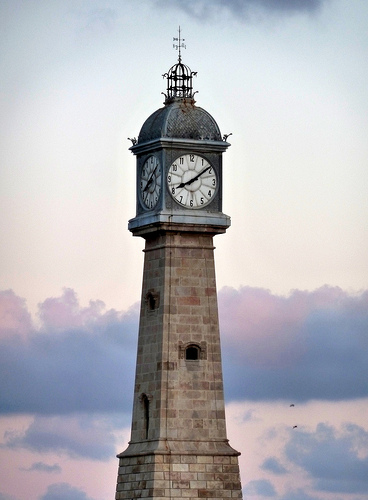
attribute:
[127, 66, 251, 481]
tower — atop, brick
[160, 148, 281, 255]
clock — brick, granite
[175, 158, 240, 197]
hand — minute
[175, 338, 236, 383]
window — large, small, under, opening, triangle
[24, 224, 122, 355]
sky — pink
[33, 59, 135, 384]
clouds — subtle, grey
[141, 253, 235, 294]
brick — white, brown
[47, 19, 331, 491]
photo — taken, evening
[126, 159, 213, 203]
numbers — gray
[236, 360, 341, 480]
birds — flying, distant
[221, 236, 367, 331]
shade — pink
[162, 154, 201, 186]
face — white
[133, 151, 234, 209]
time — displayed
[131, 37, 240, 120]
weather vane — atop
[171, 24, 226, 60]
cross — metal